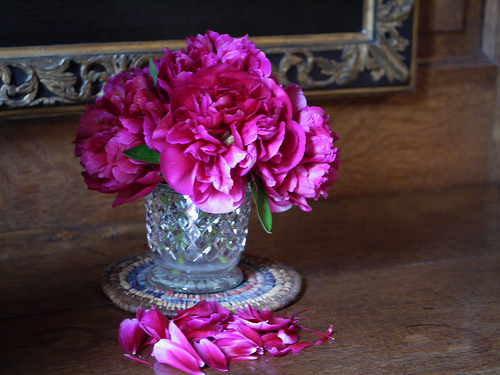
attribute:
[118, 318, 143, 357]
petal — pink, fallen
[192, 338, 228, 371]
petal — pink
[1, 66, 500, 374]
table — brown, wood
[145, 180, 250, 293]
vase — glass, clear, crystal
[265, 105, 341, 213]
flower — pink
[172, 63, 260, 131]
flower — pink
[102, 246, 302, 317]
coaster — multicolored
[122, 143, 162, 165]
leaf — green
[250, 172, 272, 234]
leaf — green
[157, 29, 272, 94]
flower — pink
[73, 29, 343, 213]
flowers — pink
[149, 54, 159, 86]
leaf — green